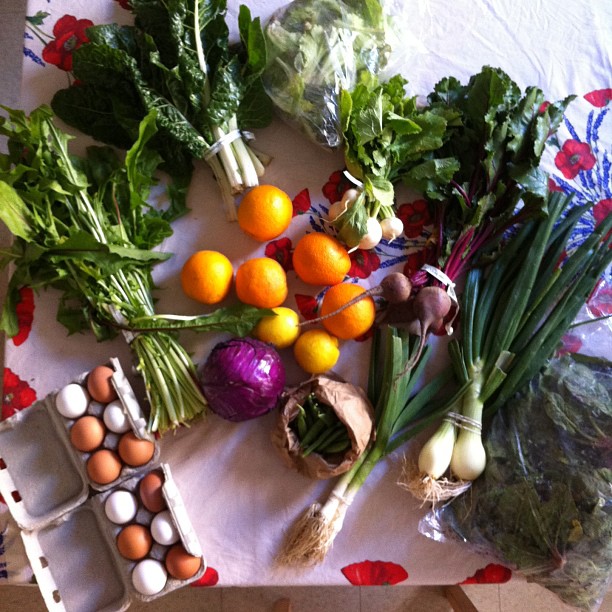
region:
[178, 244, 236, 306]
orange on top of table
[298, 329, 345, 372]
lemon on top of table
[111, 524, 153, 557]
brown inside of carton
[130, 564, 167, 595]
white egg inside carton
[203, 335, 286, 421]
red cabbage on top of table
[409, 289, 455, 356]
beet on top of table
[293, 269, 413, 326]
beet on top of table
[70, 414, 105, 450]
brown egg inside carton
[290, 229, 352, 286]
orange on top of table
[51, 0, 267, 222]
leafy greens on top of table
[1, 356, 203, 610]
cardboard carton with a dozen eggs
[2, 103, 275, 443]
arugula leaves tied into bunch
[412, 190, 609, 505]
white spring onions with green tops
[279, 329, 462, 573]
scallions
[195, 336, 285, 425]
purple onion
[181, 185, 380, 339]
five oranges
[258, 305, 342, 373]
two yellow lemons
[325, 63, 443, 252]
turnip bulbs with green tops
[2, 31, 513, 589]
white tablecloth with printed red poppies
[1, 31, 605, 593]
produce and eggs on tablecloth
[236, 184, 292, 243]
orange on table next to orange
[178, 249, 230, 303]
orange on table next to orange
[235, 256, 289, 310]
orange on table next to orange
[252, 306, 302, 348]
lemon on table next to orange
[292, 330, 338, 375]
lemon on table next to orange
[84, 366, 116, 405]
brown egg in cardboard carton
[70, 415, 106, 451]
brown egg in cardboard carton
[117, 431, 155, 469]
brown egg in cardboard carton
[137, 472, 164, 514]
brown egg in cardboard carton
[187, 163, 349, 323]
group of oranges on table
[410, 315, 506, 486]
small bunch of leeks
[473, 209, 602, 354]
green leaves on leeks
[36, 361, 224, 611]
open carton of eggs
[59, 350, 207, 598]
white and brown eggs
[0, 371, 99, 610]
grey carton with eggs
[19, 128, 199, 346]
green leaves on onions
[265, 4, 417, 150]
large head of lettuce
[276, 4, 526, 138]
lettuce on white cloth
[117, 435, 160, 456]
a brown egg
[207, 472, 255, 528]
a table cloth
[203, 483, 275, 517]
the cloth is white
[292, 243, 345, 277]
an orange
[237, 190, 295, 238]
the fruit is orange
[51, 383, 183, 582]
a carton of eggs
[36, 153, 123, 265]
green leaves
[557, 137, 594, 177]
a red flower on the table cloth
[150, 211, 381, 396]
Oranges on the table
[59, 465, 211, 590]
Brown and white eggs in a box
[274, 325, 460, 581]
Green onions on the table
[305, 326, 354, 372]
A piece of food.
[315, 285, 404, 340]
A piece of food.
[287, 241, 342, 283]
A piece of food.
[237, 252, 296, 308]
A piece of food.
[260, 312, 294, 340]
A piece of food.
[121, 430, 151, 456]
A piece of food.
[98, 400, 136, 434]
A piece of food.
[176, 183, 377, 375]
Seven orange oranges on the table.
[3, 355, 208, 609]
Carton of white and brown chicken eggs.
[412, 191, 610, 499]
A bunch of shallots on the table.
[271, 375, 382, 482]
Brown paper bag of peas on the table.